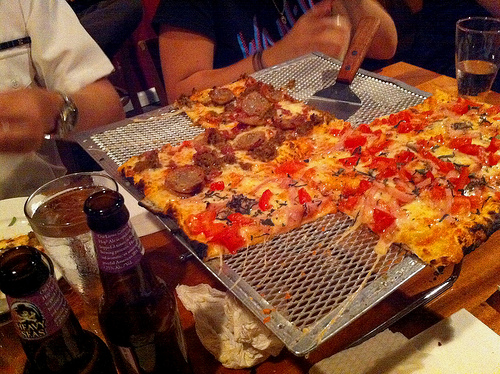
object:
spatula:
[305, 16, 382, 123]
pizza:
[116, 71, 500, 271]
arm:
[20, 0, 129, 138]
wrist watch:
[41, 92, 79, 141]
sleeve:
[17, 0, 116, 98]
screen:
[71, 51, 499, 358]